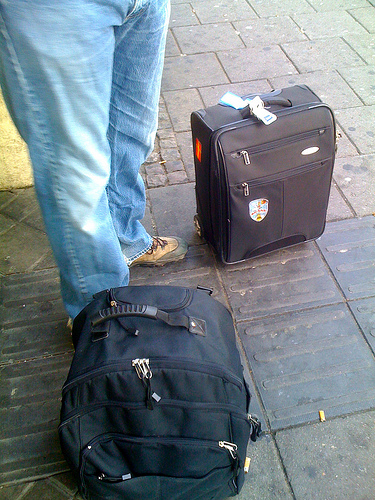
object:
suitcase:
[191, 85, 337, 267]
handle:
[240, 94, 293, 115]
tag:
[249, 103, 275, 126]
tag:
[220, 90, 249, 110]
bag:
[57, 284, 262, 500]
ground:
[0, 0, 375, 500]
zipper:
[140, 356, 153, 380]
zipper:
[219, 440, 237, 452]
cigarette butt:
[319, 409, 326, 421]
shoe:
[130, 234, 188, 268]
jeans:
[0, 0, 171, 321]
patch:
[196, 137, 202, 163]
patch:
[248, 198, 269, 223]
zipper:
[240, 150, 251, 166]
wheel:
[192, 214, 204, 239]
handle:
[89, 304, 206, 342]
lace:
[145, 237, 166, 255]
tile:
[236, 301, 374, 433]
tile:
[216, 241, 346, 320]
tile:
[3, 223, 52, 274]